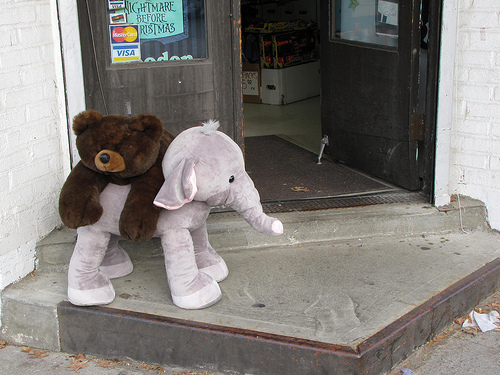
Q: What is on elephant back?
A: Bear.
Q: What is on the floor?
A: Carpet.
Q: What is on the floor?
A: Floor mat.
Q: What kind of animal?
A: Elephant.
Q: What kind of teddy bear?
A: Dark brown plush teddy bear.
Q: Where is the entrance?
A: Diagonal step entrance.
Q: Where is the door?
A: It's propped open.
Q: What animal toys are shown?
A: Elephant and a bear.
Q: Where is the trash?
A: By the steps.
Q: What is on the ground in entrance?
A: A dirty mat.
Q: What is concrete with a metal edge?
A: The step.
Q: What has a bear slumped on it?
A: Faded purple elephant.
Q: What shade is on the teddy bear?
A: Brown.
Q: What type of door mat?
A: A carpet type.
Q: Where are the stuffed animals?
A: On the stoop.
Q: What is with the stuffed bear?
A: Stuffed elephant.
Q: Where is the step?
A: In front of the door.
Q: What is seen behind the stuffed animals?
A: Door that is open.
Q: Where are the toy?
A: On the steps.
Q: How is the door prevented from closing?
A: With a doorstop.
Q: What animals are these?
A: A bear and elephant.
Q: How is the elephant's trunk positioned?
A: Down.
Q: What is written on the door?
A: Nightmare Before Christmas.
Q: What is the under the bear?
A: Elephant.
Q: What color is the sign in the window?
A: Blue.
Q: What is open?
A: Door.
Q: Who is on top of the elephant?
A: Bear.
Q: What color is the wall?
A: White.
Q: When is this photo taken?
A: Daytime.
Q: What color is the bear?
A: Brown.